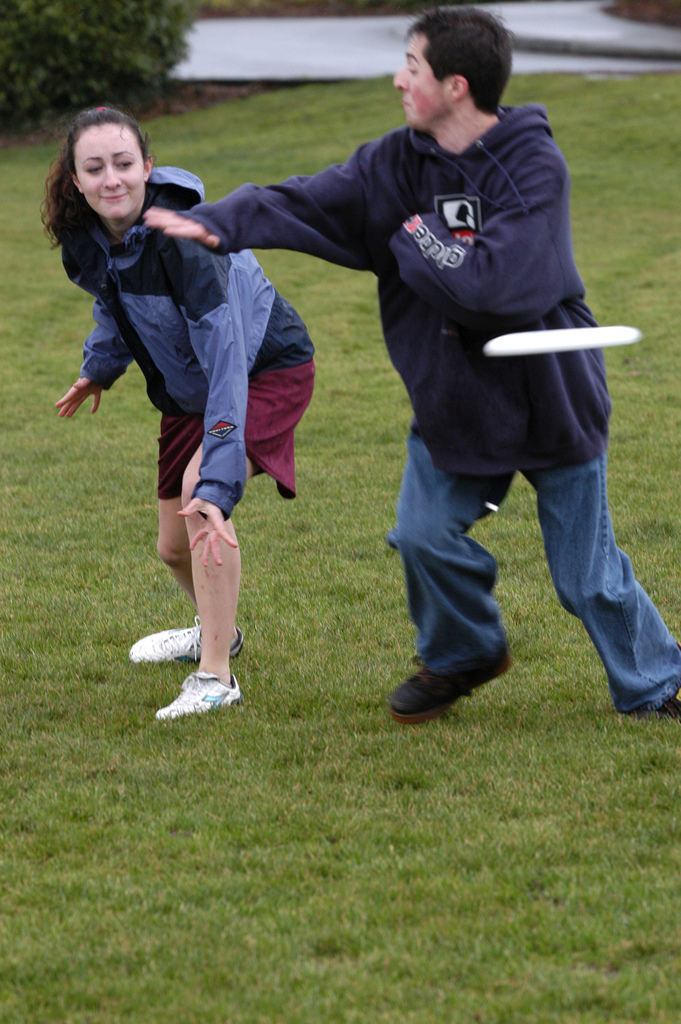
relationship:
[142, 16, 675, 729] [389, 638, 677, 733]
man wearing shoes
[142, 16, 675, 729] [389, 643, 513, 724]
man wearing shoe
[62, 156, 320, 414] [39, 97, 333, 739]
jacket belongs to girl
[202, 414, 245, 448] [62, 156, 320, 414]
label on jacket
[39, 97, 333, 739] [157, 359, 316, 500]
girl has shorts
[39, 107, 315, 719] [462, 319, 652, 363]
girl playing with disc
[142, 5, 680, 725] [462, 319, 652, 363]
man playing with disc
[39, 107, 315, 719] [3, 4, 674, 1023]
girl playing in park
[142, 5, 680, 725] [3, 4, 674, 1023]
man playing in park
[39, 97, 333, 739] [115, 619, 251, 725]
girl wearing shoes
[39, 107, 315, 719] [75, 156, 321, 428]
girl has jacket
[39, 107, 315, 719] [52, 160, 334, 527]
girl has jacket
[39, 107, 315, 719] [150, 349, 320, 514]
girl has shorts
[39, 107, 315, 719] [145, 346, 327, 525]
girl has shorts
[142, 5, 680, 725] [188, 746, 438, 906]
man in park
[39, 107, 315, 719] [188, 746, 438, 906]
girl in park